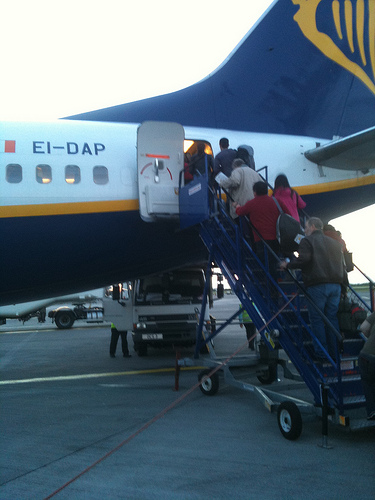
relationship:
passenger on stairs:
[223, 157, 266, 234] [180, 158, 373, 439]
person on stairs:
[238, 178, 291, 262] [180, 158, 373, 439]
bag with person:
[275, 205, 303, 255] [238, 178, 291, 262]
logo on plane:
[279, 0, 372, 101] [0, 0, 374, 308]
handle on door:
[154, 157, 162, 182] [133, 118, 187, 223]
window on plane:
[63, 164, 85, 187] [0, 0, 374, 308]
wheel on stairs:
[274, 400, 306, 442] [180, 158, 373, 439]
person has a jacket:
[238, 178, 291, 262] [288, 233, 352, 286]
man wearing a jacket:
[283, 218, 348, 361] [288, 233, 352, 286]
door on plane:
[133, 118, 187, 223] [0, 0, 374, 308]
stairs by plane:
[180, 158, 373, 439] [0, 0, 374, 308]